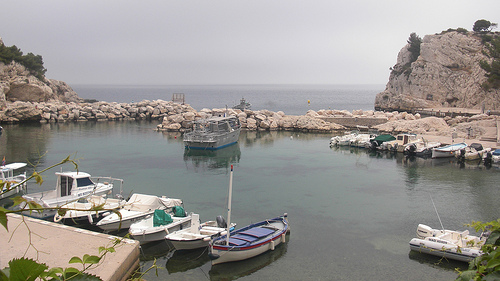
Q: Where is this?
A: This is at the harbor.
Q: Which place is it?
A: It is a harbor.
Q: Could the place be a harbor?
A: Yes, it is a harbor.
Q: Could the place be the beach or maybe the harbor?
A: It is the harbor.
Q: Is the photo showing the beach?
A: No, the picture is showing the harbor.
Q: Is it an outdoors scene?
A: Yes, it is outdoors.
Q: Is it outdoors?
A: Yes, it is outdoors.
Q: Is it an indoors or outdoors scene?
A: It is outdoors.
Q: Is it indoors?
A: No, it is outdoors.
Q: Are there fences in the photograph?
A: No, there are no fences.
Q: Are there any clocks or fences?
A: No, there are no fences or clocks.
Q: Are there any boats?
A: Yes, there is a boat.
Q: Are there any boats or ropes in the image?
A: Yes, there is a boat.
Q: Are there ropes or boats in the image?
A: Yes, there is a boat.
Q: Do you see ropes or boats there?
A: Yes, there is a boat.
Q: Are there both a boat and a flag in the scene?
A: No, there is a boat but no flags.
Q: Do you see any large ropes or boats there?
A: Yes, there is a large boat.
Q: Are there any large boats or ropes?
A: Yes, there is a large boat.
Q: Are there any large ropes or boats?
A: Yes, there is a large boat.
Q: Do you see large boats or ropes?
A: Yes, there is a large boat.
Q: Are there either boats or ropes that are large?
A: Yes, the boat is large.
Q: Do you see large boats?
A: Yes, there is a large boat.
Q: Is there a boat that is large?
A: Yes, there is a boat that is large.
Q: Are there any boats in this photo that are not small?
A: Yes, there is a large boat.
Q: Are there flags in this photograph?
A: No, there are no flags.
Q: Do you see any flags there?
A: No, there are no flags.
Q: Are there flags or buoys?
A: No, there are no flags or buoys.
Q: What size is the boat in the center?
A: The boat is large.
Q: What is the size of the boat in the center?
A: The boat is large.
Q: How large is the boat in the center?
A: The boat is large.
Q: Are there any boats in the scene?
A: Yes, there is a boat.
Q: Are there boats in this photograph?
A: Yes, there is a boat.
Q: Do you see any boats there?
A: Yes, there is a boat.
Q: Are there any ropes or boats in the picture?
A: Yes, there is a boat.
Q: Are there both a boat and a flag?
A: No, there is a boat but no flags.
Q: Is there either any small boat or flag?
A: Yes, there is a small boat.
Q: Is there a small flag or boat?
A: Yes, there is a small boat.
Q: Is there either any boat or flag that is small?
A: Yes, the boat is small.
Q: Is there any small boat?
A: Yes, there is a small boat.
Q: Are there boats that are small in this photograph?
A: Yes, there is a small boat.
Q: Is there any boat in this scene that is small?
A: Yes, there is a boat that is small.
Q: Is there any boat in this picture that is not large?
A: Yes, there is a small boat.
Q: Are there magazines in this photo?
A: No, there are no magazines.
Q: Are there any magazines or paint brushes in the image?
A: No, there are no magazines or paint brushes.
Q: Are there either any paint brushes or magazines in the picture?
A: No, there are no magazines or paint brushes.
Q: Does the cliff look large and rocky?
A: Yes, the cliff is large and rocky.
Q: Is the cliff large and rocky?
A: Yes, the cliff is large and rocky.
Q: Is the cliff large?
A: Yes, the cliff is large.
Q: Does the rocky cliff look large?
A: Yes, the cliff is large.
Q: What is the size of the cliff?
A: The cliff is large.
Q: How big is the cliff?
A: The cliff is large.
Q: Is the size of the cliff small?
A: No, the cliff is large.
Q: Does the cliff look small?
A: No, the cliff is large.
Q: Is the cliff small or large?
A: The cliff is large.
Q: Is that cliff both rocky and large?
A: Yes, the cliff is rocky and large.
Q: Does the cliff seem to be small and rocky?
A: No, the cliff is rocky but large.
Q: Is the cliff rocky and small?
A: No, the cliff is rocky but large.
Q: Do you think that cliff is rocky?
A: Yes, the cliff is rocky.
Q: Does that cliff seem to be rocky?
A: Yes, the cliff is rocky.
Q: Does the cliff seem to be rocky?
A: Yes, the cliff is rocky.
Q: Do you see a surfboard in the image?
A: No, there are no surfboards.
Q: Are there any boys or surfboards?
A: No, there are no surfboards or boys.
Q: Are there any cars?
A: No, there are no cars.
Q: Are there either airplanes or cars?
A: No, there are no cars or airplanes.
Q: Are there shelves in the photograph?
A: No, there are no shelves.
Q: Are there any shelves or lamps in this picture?
A: No, there are no shelves or lamps.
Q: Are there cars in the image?
A: No, there are no cars.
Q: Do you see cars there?
A: No, there are no cars.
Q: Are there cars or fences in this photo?
A: No, there are no cars or fences.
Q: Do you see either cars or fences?
A: No, there are no cars or fences.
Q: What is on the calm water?
A: The boats are on the water.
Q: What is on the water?
A: The boats are on the water.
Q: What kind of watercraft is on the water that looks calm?
A: The watercraft is boats.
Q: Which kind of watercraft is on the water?
A: The watercraft is boats.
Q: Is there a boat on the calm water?
A: Yes, there are boats on the water.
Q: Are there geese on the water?
A: No, there are boats on the water.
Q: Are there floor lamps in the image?
A: No, there are no floor lamps.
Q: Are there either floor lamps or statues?
A: No, there are no floor lamps or statues.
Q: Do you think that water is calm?
A: Yes, the water is calm.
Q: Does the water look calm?
A: Yes, the water is calm.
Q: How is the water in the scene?
A: The water is calm.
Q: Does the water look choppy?
A: No, the water is calm.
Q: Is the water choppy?
A: No, the water is calm.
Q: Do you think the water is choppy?
A: No, the water is calm.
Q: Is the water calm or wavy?
A: The water is calm.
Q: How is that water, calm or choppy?
A: The water is calm.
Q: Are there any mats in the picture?
A: No, there are no mats.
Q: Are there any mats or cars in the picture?
A: No, there are no mats or cars.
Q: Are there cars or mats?
A: No, there are no mats or cars.